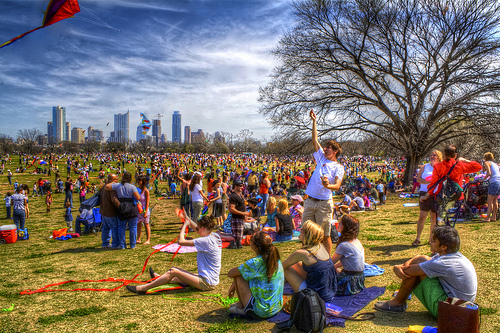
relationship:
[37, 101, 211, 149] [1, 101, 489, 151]
city in distance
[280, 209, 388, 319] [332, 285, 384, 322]
people sitting on blanket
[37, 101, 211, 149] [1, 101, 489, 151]
city in background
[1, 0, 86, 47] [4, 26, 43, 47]
kite has tail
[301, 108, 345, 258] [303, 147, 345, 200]
man wearing white tshirt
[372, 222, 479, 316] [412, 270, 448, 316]
person wearing green shorts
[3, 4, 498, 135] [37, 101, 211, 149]
sky over a city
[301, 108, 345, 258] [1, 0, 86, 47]
man holding kite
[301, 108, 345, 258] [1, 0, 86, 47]
man flying a kite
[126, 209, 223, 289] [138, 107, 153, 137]
man flying a kite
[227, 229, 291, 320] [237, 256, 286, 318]
woman wearing shirt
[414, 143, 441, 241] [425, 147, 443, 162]
woman has red hair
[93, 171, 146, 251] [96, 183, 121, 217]
couple with arms around each other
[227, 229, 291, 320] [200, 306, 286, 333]
woman sitting on ground